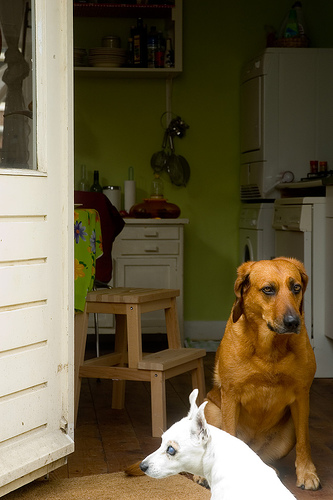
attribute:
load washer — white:
[229, 202, 267, 272]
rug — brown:
[39, 466, 192, 498]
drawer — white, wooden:
[120, 239, 179, 255]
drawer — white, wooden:
[120, 224, 181, 239]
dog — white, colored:
[138, 385, 291, 495]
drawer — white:
[119, 241, 182, 256]